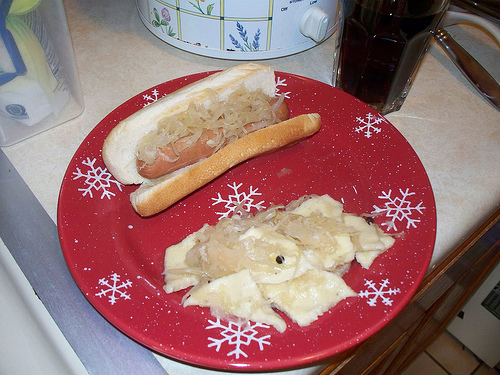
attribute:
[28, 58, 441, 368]
plate — red, round, white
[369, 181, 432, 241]
snowflakes — white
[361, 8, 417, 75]
soda — dark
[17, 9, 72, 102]
silverware — plastic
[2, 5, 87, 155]
canister — plastic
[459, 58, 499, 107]
handle — metal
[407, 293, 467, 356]
doors — wooden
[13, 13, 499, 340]
table — formica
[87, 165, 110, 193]
stars — white